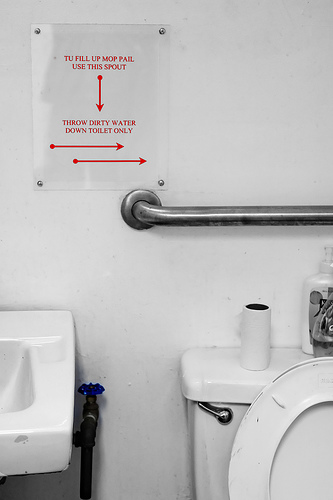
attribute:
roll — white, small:
[233, 298, 273, 375]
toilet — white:
[179, 339, 332, 496]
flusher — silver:
[194, 398, 234, 428]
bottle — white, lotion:
[302, 272, 331, 351]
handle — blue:
[74, 380, 108, 399]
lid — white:
[181, 344, 332, 401]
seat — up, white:
[229, 355, 332, 499]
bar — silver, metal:
[117, 189, 332, 231]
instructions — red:
[42, 51, 148, 171]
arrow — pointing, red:
[43, 139, 127, 153]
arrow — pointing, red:
[67, 155, 150, 170]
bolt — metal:
[32, 27, 44, 36]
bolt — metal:
[155, 26, 168, 37]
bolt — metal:
[153, 178, 165, 188]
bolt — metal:
[35, 177, 47, 187]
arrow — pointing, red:
[92, 71, 108, 114]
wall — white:
[1, 2, 332, 346]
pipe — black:
[74, 416, 98, 499]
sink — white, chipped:
[1, 302, 80, 481]